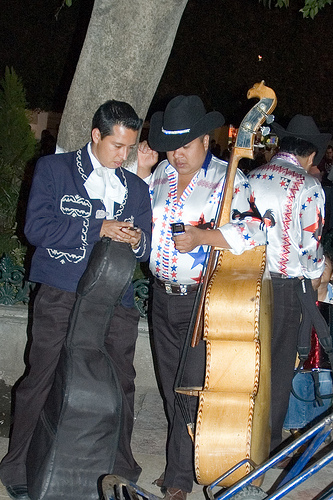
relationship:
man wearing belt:
[135, 92, 267, 499] [151, 275, 197, 304]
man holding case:
[44, 108, 134, 284] [61, 239, 123, 499]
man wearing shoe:
[135, 92, 267, 499] [151, 471, 166, 487]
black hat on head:
[147, 94, 224, 152] [149, 116, 209, 176]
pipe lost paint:
[278, 433, 308, 462] [163, 215, 226, 245]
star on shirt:
[188, 245, 211, 270] [144, 160, 261, 293]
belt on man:
[158, 261, 266, 286] [137, 105, 243, 339]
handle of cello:
[216, 72, 282, 179] [197, 65, 286, 473]